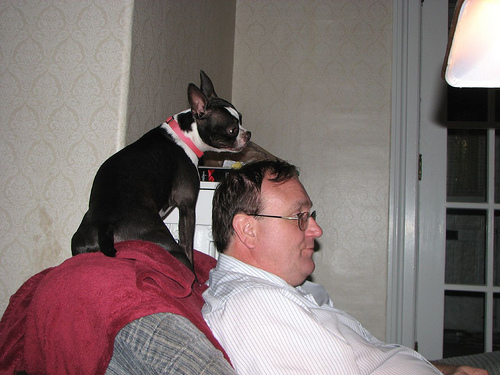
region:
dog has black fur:
[71, 91, 258, 300]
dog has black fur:
[96, 129, 186, 224]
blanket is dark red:
[26, 265, 143, 367]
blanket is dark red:
[51, 245, 109, 372]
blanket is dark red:
[61, 243, 184, 335]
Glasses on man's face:
[252, 189, 328, 251]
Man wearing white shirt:
[216, 267, 317, 354]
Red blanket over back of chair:
[58, 272, 174, 371]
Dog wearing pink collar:
[158, 109, 218, 190]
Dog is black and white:
[93, 90, 223, 270]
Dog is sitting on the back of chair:
[64, 102, 206, 320]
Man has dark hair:
[213, 160, 283, 237]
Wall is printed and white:
[24, 65, 90, 162]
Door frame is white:
[387, 137, 423, 299]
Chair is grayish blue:
[138, 332, 208, 372]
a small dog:
[71, 67, 291, 310]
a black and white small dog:
[23, 60, 285, 262]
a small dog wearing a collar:
[36, 55, 271, 290]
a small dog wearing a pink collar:
[26, 54, 278, 270]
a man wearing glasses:
[191, 120, 334, 309]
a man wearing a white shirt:
[224, 148, 430, 370]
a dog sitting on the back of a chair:
[4, 83, 436, 370]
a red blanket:
[0, 237, 262, 373]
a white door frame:
[393, 0, 494, 366]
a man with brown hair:
[203, 135, 352, 330]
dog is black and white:
[58, 99, 298, 326]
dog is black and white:
[86, 124, 213, 259]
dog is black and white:
[111, 87, 182, 232]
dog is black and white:
[126, 140, 231, 222]